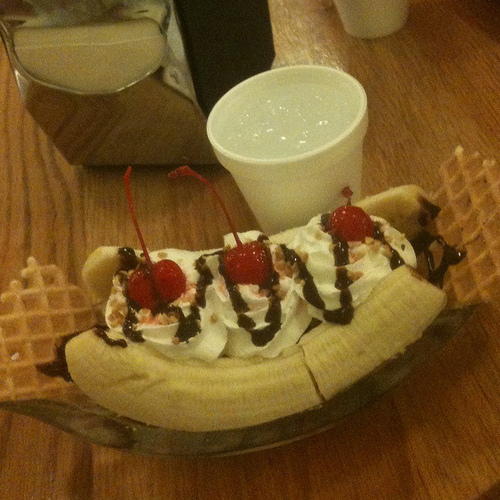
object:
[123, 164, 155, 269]
stem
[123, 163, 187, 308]
cherry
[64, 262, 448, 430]
banana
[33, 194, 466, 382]
chocolate sauce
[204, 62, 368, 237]
cup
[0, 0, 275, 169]
napkin holder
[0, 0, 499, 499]
table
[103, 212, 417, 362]
whipped cream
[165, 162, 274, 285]
cherry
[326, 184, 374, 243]
cherry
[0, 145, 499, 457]
banana split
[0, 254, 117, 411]
waffle cone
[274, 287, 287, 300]
peanut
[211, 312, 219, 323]
peanut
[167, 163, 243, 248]
stem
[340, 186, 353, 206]
stem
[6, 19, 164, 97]
paper nakins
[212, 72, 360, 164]
water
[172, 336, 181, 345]
peanut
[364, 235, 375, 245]
peanut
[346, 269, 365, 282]
peanut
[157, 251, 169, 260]
peanut